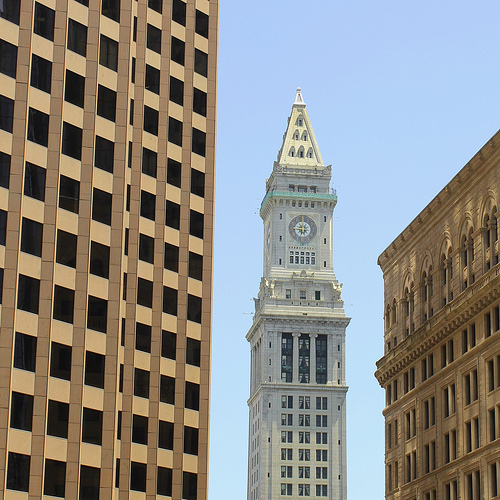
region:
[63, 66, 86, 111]
black window in tan building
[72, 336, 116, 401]
black window in tan building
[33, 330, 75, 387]
black window in tan building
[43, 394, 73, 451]
black window in tan building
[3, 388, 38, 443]
black window in tan building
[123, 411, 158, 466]
black window in tan building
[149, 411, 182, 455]
black window in tan building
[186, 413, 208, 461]
black window in tan building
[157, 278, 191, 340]
black window in tan building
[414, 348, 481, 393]
black window in tan building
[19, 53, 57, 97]
black window in brown building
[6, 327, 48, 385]
black window in brown building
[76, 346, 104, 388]
black window in brown building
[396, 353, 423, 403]
black window in brown building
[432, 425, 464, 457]
black window in brown building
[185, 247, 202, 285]
black window in brown building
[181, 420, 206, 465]
black window in brown building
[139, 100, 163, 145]
black window in brown building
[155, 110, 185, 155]
black window in brown building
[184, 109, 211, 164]
black window in brown building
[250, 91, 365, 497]
a tall white building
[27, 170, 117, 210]
the windows on the tanned building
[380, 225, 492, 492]
the building is brown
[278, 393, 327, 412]
windows on the white building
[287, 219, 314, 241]
a clock on the white building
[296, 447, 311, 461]
curtains in the window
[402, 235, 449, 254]
a shadow on the building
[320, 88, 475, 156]
the sky is clear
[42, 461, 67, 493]
the window is black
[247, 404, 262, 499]
the side of the building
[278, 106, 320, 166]
six windows in a yellow triangle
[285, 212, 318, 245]
clock has golden hands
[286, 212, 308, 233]
clock hands point to 9 o' clock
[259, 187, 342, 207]
balcony near the top of building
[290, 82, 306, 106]
white triangle with a white ball on top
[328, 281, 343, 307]
statue on the right side of building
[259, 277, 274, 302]
statute on the left side of building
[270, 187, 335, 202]
balcony is green with railings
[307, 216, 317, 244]
numbers are gold on grey background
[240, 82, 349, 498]
tall white building in the center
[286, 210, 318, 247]
Clock on side of building.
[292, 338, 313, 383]
White drapes in windows.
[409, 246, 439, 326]
Domed windows in building.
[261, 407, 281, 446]
Gray brick on building wall.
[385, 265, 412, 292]
Tan bricks on side of building.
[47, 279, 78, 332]
Black window in side of building.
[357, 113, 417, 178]
Blue sky in the background.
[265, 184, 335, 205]
Turquoise railing on top of building.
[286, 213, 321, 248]
Gold colored numbers and hands on clock.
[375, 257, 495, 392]
Stone ledge on side of building.